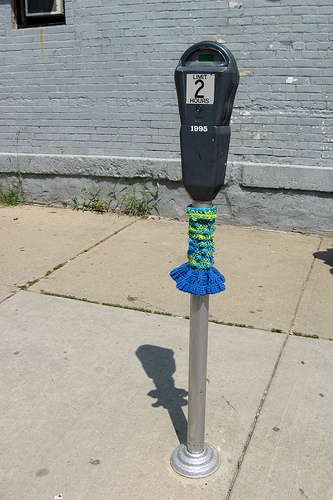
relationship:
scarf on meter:
[175, 207, 228, 298] [172, 42, 240, 479]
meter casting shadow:
[172, 42, 240, 479] [139, 346, 191, 445]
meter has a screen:
[172, 42, 240, 479] [199, 51, 213, 61]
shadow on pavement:
[139, 346, 191, 445] [1, 204, 331, 497]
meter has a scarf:
[172, 42, 240, 479] [175, 207, 228, 298]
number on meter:
[190, 124, 209, 134] [172, 42, 240, 479]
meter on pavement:
[172, 42, 240, 479] [1, 204, 331, 497]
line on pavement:
[3, 286, 330, 347] [1, 204, 331, 497]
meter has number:
[172, 42, 240, 479] [190, 124, 209, 134]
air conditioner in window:
[25, 4, 63, 16] [9, 3, 72, 28]